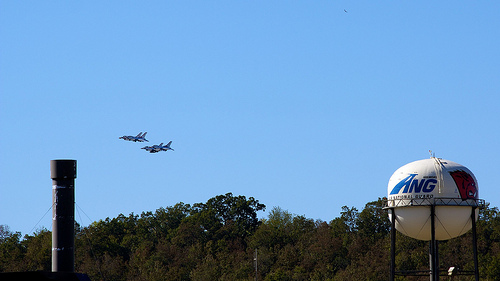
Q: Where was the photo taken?
A: It was taken at the town.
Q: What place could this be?
A: It is a town.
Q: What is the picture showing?
A: It is showing a town.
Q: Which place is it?
A: It is a town.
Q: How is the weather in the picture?
A: It is clear.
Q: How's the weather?
A: It is clear.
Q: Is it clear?
A: Yes, it is clear.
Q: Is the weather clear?
A: Yes, it is clear.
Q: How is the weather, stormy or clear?
A: It is clear.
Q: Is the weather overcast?
A: No, it is clear.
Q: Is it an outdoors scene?
A: Yes, it is outdoors.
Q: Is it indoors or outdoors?
A: It is outdoors.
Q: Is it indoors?
A: No, it is outdoors.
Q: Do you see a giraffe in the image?
A: No, there are no giraffes.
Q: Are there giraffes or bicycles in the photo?
A: No, there are no giraffes or bicycles.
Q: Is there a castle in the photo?
A: No, there are no castles.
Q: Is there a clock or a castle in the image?
A: No, there are no castles or clocks.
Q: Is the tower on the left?
A: Yes, the tower is on the left of the image.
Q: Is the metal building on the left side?
A: Yes, the tower is on the left of the image.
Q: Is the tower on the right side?
A: No, the tower is on the left of the image.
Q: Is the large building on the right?
A: No, the tower is on the left of the image.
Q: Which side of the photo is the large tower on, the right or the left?
A: The tower is on the left of the image.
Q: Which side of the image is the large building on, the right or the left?
A: The tower is on the left of the image.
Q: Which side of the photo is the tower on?
A: The tower is on the left of the image.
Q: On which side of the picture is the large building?
A: The tower is on the left of the image.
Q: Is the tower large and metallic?
A: Yes, the tower is large and metallic.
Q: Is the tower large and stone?
A: No, the tower is large but metallic.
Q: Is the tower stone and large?
A: No, the tower is large but metallic.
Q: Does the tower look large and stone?
A: No, the tower is large but metallic.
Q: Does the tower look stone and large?
A: No, the tower is large but metallic.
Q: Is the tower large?
A: Yes, the tower is large.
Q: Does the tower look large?
A: Yes, the tower is large.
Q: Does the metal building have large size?
A: Yes, the tower is large.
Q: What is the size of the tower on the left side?
A: The tower is large.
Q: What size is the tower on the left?
A: The tower is large.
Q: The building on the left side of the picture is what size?
A: The tower is large.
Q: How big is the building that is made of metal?
A: The tower is large.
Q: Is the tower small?
A: No, the tower is large.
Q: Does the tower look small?
A: No, the tower is large.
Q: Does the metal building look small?
A: No, the tower is large.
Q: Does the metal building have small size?
A: No, the tower is large.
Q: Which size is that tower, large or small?
A: The tower is large.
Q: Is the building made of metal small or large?
A: The tower is large.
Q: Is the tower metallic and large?
A: Yes, the tower is metallic and large.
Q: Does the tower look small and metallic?
A: No, the tower is metallic but large.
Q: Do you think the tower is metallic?
A: Yes, the tower is metallic.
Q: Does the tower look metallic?
A: Yes, the tower is metallic.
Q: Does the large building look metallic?
A: Yes, the tower is metallic.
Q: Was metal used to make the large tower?
A: Yes, the tower is made of metal.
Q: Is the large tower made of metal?
A: Yes, the tower is made of metal.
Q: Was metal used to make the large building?
A: Yes, the tower is made of metal.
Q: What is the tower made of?
A: The tower is made of metal.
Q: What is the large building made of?
A: The tower is made of metal.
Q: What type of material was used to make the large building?
A: The tower is made of metal.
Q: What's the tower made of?
A: The tower is made of metal.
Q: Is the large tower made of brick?
A: No, the tower is made of metal.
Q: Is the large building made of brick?
A: No, the tower is made of metal.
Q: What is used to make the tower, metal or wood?
A: The tower is made of metal.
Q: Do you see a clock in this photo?
A: No, there are no clocks.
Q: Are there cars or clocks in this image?
A: No, there are no clocks or cars.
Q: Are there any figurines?
A: No, there are no figurines.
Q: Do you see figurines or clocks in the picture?
A: No, there are no figurines or clocks.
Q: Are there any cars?
A: No, there are no cars.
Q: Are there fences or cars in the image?
A: No, there are no cars or fences.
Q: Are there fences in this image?
A: No, there are no fences.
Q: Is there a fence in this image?
A: No, there are no fences.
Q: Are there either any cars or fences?
A: No, there are no fences or cars.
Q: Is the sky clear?
A: Yes, the sky is clear.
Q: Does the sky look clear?
A: Yes, the sky is clear.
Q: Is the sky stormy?
A: No, the sky is clear.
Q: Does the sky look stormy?
A: No, the sky is clear.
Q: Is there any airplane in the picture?
A: Yes, there is an airplane.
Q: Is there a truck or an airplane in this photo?
A: Yes, there is an airplane.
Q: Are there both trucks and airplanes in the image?
A: No, there is an airplane but no trucks.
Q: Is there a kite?
A: No, there are no kites.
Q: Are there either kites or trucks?
A: No, there are no kites or trucks.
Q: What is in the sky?
A: The airplane is in the sky.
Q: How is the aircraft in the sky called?
A: The aircraft is an airplane.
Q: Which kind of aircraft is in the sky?
A: The aircraft is an airplane.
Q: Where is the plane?
A: The plane is in the sky.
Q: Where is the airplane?
A: The plane is in the sky.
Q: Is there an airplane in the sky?
A: Yes, there is an airplane in the sky.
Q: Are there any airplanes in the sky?
A: Yes, there is an airplane in the sky.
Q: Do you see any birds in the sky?
A: No, there is an airplane in the sky.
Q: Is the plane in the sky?
A: Yes, the plane is in the sky.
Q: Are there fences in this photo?
A: No, there are no fences.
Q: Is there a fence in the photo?
A: No, there are no fences.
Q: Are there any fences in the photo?
A: No, there are no fences.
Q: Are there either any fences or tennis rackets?
A: No, there are no fences or tennis rackets.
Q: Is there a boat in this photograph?
A: No, there are no boats.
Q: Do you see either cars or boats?
A: No, there are no boats or cars.